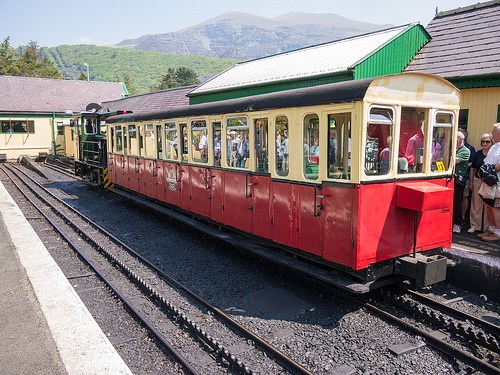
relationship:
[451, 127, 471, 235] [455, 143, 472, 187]
man wearing shirt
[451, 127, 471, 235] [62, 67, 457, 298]
man waiting for train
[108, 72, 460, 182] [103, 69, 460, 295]
top of train car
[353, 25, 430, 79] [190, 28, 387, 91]
green building with white roof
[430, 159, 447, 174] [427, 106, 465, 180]
sign in back of window